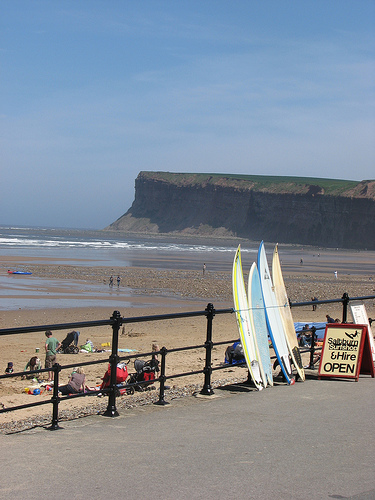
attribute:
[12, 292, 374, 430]
rails — black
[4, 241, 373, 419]
beach — small, yellow, brown, sandy, tiny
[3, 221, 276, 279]
water — low, weak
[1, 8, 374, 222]
sky — huge, big, wide, open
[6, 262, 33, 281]
boat — blue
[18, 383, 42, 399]
toy — yellow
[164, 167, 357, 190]
grass — green, short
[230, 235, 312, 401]
surfboards — leaning, blue, white, yellow, standing